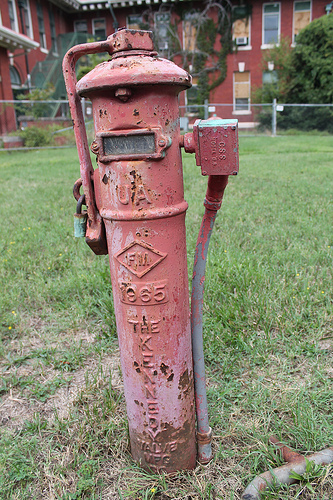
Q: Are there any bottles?
A: No, there are no bottles.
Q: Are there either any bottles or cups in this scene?
A: No, there are no bottles or cups.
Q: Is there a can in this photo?
A: No, there are no cans.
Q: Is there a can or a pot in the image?
A: No, there are no cans or pots.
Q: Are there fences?
A: Yes, there is a fence.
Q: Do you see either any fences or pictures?
A: Yes, there is a fence.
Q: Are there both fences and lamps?
A: No, there is a fence but no lamps.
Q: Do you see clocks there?
A: No, there are no clocks.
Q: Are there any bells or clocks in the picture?
A: No, there are no clocks or bells.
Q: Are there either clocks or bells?
A: No, there are no clocks or bells.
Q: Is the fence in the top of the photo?
A: Yes, the fence is in the top of the image.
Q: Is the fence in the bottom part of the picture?
A: No, the fence is in the top of the image.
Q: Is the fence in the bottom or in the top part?
A: The fence is in the top of the image.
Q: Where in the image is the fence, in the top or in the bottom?
A: The fence is in the top of the image.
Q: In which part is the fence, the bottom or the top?
A: The fence is in the top of the image.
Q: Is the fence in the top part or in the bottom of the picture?
A: The fence is in the top of the image.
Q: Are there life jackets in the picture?
A: No, there are no life jackets.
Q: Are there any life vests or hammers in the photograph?
A: No, there are no life vests or hammers.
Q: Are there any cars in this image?
A: No, there are no cars.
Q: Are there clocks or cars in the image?
A: No, there are no cars or clocks.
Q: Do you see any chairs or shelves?
A: No, there are no chairs or shelves.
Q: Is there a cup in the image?
A: No, there are no cups.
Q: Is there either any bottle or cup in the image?
A: No, there are no cups or bottles.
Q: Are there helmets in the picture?
A: No, there are no helmets.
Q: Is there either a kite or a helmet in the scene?
A: No, there are no helmets or kites.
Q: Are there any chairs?
A: No, there are no chairs.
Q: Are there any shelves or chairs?
A: No, there are no chairs or shelves.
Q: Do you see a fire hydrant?
A: Yes, there is a fire hydrant.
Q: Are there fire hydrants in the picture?
A: Yes, there is a fire hydrant.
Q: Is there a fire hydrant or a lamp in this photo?
A: Yes, there is a fire hydrant.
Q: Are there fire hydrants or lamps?
A: Yes, there is a fire hydrant.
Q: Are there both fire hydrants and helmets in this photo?
A: No, there is a fire hydrant but no helmets.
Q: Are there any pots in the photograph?
A: No, there are no pots.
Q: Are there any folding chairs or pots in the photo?
A: No, there are no pots or folding chairs.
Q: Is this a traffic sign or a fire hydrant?
A: This is a fire hydrant.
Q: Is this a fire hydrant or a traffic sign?
A: This is a fire hydrant.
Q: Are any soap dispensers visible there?
A: No, there are no soap dispensers.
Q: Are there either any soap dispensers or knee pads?
A: No, there are no soap dispensers or knee pads.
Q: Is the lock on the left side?
A: Yes, the lock is on the left of the image.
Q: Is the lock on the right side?
A: No, the lock is on the left of the image.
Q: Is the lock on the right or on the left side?
A: The lock is on the left of the image.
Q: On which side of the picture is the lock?
A: The lock is on the left of the image.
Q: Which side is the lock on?
A: The lock is on the left of the image.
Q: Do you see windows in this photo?
A: Yes, there is a window.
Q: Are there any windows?
A: Yes, there is a window.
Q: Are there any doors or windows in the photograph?
A: Yes, there is a window.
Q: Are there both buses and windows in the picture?
A: No, there is a window but no buses.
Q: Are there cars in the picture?
A: No, there are no cars.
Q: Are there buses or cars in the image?
A: No, there are no cars or buses.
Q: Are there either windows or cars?
A: Yes, there is a window.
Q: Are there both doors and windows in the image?
A: No, there is a window but no doors.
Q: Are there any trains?
A: No, there are no trains.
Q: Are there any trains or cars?
A: No, there are no trains or cars.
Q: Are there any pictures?
A: No, there are no pictures.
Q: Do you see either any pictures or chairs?
A: No, there are no pictures or chairs.